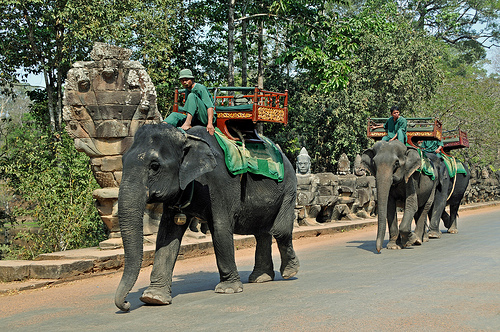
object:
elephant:
[435, 149, 470, 235]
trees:
[264, 0, 452, 174]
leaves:
[362, 41, 397, 92]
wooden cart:
[367, 117, 444, 149]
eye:
[149, 159, 161, 171]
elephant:
[107, 112, 310, 300]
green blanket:
[435, 152, 468, 179]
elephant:
[114, 122, 301, 313]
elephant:
[444, 153, 468, 235]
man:
[418, 119, 446, 161]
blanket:
[406, 141, 437, 182]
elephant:
[360, 140, 442, 254]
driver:
[157, 68, 217, 137]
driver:
[381, 106, 407, 144]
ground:
[0, 206, 499, 331]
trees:
[0, 113, 112, 262]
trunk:
[113, 149, 149, 312]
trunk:
[370, 155, 398, 252]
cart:
[173, 85, 289, 141]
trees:
[0, 0, 232, 120]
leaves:
[285, 21, 310, 52]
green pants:
[164, 92, 209, 128]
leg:
[140, 197, 195, 305]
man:
[158, 69, 214, 137]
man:
[382, 106, 409, 145]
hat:
[177, 68, 196, 79]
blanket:
[213, 124, 286, 183]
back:
[214, 86, 289, 141]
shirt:
[382, 116, 407, 139]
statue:
[61, 41, 164, 250]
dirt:
[0, 205, 499, 319]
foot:
[140, 282, 175, 305]